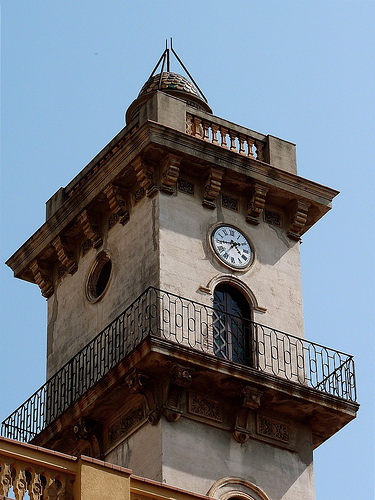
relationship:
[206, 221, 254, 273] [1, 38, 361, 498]
clock on building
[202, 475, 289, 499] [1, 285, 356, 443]
round under metal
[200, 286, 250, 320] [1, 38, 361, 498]
window on side of building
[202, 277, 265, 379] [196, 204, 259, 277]
door under clock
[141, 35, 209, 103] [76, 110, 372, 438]
pipes come to point on building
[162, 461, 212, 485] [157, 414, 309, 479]
edge of shade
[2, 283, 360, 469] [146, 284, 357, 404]
balcony made of wrought iron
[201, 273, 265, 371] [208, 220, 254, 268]
door beneath clock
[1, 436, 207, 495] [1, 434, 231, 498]
part of fence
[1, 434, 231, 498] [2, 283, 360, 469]
fence to balcony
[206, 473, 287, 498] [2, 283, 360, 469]
doorway under balcony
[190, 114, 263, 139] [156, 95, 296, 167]
railing to roof balcony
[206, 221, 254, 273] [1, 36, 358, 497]
clock on tower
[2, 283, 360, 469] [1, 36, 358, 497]
balcony around tower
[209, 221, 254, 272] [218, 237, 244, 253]
clock has hands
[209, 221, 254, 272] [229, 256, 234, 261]
clock has roman numerals